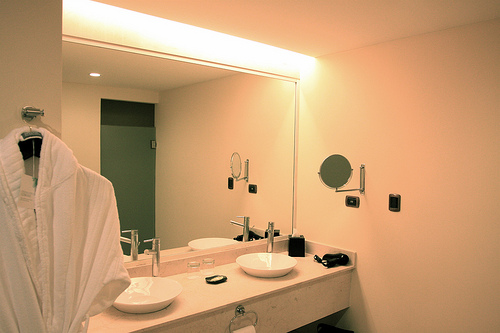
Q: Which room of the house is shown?
A: It is a bathroom.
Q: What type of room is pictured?
A: It is a bathroom.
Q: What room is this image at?
A: It is at the bathroom.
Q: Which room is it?
A: It is a bathroom.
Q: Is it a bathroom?
A: Yes, it is a bathroom.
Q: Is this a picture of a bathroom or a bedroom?
A: It is showing a bathroom.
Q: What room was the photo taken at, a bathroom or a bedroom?
A: It was taken at a bathroom.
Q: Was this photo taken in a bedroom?
A: No, the picture was taken in a bathroom.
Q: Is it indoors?
A: Yes, it is indoors.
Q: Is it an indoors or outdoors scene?
A: It is indoors.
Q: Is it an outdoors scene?
A: No, it is indoors.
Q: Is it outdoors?
A: No, it is indoors.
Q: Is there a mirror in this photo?
A: Yes, there is a mirror.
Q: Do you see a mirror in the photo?
A: Yes, there is a mirror.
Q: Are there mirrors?
A: Yes, there is a mirror.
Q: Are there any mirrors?
A: Yes, there is a mirror.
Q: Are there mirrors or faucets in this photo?
A: Yes, there is a mirror.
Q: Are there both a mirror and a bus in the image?
A: No, there is a mirror but no buses.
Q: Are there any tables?
A: No, there are no tables.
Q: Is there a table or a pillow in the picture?
A: No, there are no tables or pillows.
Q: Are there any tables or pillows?
A: No, there are no tables or pillows.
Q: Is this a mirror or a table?
A: This is a mirror.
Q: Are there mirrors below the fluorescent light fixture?
A: Yes, there is a mirror below the light fixture.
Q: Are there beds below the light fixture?
A: No, there is a mirror below the light fixture.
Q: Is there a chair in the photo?
A: No, there are no chairs.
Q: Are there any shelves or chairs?
A: No, there are no chairs or shelves.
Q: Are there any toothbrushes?
A: No, there are no toothbrushes.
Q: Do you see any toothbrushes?
A: No, there are no toothbrushes.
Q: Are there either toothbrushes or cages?
A: No, there are no toothbrushes or cages.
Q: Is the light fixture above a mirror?
A: Yes, the light fixture is above a mirror.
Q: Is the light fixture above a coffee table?
A: No, the light fixture is above a mirror.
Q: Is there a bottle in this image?
A: No, there are no bottles.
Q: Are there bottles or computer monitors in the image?
A: No, there are no bottles or computer monitors.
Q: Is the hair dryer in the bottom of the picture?
A: Yes, the hair dryer is in the bottom of the image.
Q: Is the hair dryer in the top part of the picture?
A: No, the hair dryer is in the bottom of the image.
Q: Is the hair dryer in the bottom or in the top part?
A: The hair dryer is in the bottom of the image.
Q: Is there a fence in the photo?
A: No, there are no fences.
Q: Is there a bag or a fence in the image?
A: No, there are no fences or bags.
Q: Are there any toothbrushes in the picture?
A: No, there are no toothbrushes.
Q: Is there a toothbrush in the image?
A: No, there are no toothbrushes.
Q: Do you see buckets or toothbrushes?
A: No, there are no toothbrushes or buckets.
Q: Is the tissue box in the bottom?
A: Yes, the tissue box is in the bottom of the image.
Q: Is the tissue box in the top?
A: No, the tissue box is in the bottom of the image.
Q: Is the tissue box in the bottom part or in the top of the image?
A: The tissue box is in the bottom of the image.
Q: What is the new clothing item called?
A: The clothing item is a robe.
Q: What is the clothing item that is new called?
A: The clothing item is a robe.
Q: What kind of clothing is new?
A: The clothing is a robe.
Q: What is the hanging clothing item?
A: The clothing item is a robe.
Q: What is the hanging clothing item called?
A: The clothing item is a robe.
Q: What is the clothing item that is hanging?
A: The clothing item is a robe.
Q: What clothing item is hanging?
A: The clothing item is a robe.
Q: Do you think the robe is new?
A: Yes, the robe is new.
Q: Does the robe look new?
A: Yes, the robe is new.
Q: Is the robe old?
A: No, the robe is new.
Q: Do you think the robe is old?
A: No, the robe is new.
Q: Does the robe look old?
A: No, the robe is new.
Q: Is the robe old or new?
A: The robe is new.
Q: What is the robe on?
A: The robe is on the wall.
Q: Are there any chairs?
A: No, there are no chairs.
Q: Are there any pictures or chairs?
A: No, there are no chairs or pictures.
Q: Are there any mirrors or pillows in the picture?
A: Yes, there is a mirror.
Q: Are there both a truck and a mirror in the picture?
A: No, there is a mirror but no trucks.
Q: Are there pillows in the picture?
A: No, there are no pillows.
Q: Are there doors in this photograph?
A: Yes, there is a door.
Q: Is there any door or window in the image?
A: Yes, there is a door.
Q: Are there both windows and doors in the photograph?
A: No, there is a door but no windows.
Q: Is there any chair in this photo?
A: No, there are no chairs.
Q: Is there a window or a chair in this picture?
A: No, there are no chairs or windows.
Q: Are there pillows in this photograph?
A: No, there are no pillows.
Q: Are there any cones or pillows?
A: No, there are no pillows or cones.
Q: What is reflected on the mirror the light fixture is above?
A: The sink is reflected on the mirror.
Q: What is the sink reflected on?
A: The sink is reflected on the mirror.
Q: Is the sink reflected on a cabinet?
A: No, the sink is reflected on a mirror.